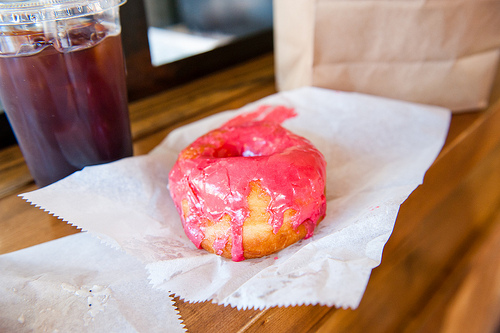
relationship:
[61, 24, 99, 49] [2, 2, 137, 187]
ice cube inside of cup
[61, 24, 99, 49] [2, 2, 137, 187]
ice cube in a cup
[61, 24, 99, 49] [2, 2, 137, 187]
ice cube inside a cup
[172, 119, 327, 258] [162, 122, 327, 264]
icing on top of donut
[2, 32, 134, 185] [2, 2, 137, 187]
liquid inside of cup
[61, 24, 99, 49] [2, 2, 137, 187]
ice cube in cup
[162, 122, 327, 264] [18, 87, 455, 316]
donut on top of paper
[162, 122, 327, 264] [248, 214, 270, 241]
donut has part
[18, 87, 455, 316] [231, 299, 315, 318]
paper has edge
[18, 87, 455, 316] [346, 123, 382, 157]
paper has part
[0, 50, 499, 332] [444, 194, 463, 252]
table has part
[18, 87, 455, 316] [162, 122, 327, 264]
paper under donut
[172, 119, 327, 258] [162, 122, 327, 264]
icing on side of donut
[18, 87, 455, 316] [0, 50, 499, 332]
paper on top of table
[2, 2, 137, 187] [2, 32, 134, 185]
cup has liquid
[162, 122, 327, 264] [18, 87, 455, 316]
donut sitting on paper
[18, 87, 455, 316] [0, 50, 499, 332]
paper sitting on table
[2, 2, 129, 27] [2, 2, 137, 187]
top on top of cup